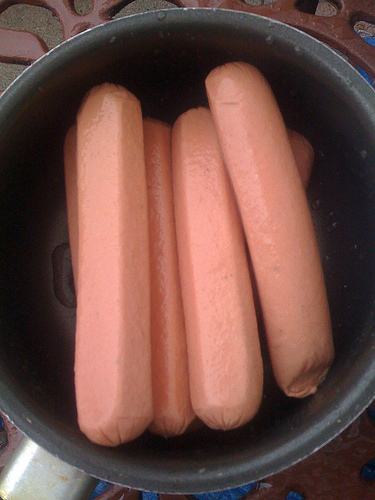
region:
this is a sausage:
[203, 66, 340, 390]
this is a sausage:
[166, 114, 249, 429]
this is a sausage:
[65, 92, 146, 438]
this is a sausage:
[137, 109, 190, 451]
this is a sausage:
[165, 101, 258, 425]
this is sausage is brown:
[71, 103, 148, 453]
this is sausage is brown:
[60, 120, 95, 283]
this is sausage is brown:
[137, 127, 210, 437]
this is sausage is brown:
[168, 101, 266, 439]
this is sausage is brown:
[208, 70, 350, 389]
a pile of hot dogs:
[58, 48, 329, 451]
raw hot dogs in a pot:
[2, 11, 372, 490]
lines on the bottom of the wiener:
[204, 409, 242, 435]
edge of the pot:
[4, 408, 374, 498]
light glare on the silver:
[5, 447, 38, 492]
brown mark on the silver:
[58, 473, 67, 482]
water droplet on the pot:
[155, 9, 168, 24]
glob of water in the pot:
[44, 240, 82, 323]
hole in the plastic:
[352, 10, 374, 48]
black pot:
[1, 6, 372, 498]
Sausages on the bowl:
[79, 178, 245, 305]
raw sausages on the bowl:
[96, 288, 259, 400]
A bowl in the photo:
[100, 20, 178, 55]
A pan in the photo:
[32, 404, 71, 480]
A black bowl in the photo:
[148, 450, 235, 490]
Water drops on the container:
[140, 5, 172, 39]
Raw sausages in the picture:
[90, 199, 320, 411]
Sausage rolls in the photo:
[67, 215, 322, 400]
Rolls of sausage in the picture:
[92, 257, 306, 388]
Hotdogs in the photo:
[95, 106, 280, 276]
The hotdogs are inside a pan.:
[10, 19, 373, 477]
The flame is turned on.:
[81, 472, 251, 493]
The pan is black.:
[1, 90, 69, 218]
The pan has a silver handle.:
[0, 396, 98, 498]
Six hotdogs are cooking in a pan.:
[60, 91, 321, 213]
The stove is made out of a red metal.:
[0, 0, 87, 60]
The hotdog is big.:
[200, 41, 335, 386]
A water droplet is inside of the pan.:
[28, 225, 85, 309]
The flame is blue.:
[195, 474, 265, 499]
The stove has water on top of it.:
[303, 1, 373, 56]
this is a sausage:
[202, 60, 365, 418]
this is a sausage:
[171, 102, 265, 422]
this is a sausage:
[74, 81, 144, 454]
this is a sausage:
[124, 109, 210, 442]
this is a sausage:
[245, 214, 340, 391]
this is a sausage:
[135, 126, 197, 311]